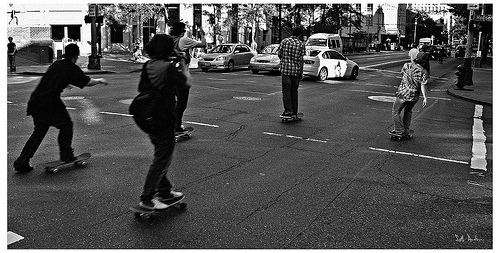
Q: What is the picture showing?
A: It is showing a road.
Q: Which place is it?
A: It is a road.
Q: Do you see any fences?
A: No, there are no fences.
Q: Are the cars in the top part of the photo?
A: Yes, the cars are in the top of the image.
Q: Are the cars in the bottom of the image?
A: No, the cars are in the top of the image.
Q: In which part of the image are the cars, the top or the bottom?
A: The cars are in the top of the image.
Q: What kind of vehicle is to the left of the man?
A: The vehicles are cars.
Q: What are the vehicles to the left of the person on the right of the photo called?
A: The vehicles are cars.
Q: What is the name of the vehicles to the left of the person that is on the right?
A: The vehicles are cars.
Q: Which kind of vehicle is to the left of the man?
A: The vehicles are cars.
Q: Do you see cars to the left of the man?
A: Yes, there are cars to the left of the man.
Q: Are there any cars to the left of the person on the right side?
A: Yes, there are cars to the left of the man.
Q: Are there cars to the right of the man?
A: No, the cars are to the left of the man.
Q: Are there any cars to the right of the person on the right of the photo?
A: No, the cars are to the left of the man.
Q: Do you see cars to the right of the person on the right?
A: No, the cars are to the left of the man.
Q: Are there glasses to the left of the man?
A: No, there are cars to the left of the man.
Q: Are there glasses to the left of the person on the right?
A: No, there are cars to the left of the man.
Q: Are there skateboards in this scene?
A: Yes, there is a skateboard.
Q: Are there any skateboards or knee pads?
A: Yes, there is a skateboard.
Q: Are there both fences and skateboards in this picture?
A: No, there is a skateboard but no fences.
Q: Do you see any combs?
A: No, there are no combs.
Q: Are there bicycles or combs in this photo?
A: No, there are no combs or bicycles.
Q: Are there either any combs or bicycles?
A: No, there are no combs or bicycles.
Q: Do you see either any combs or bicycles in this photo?
A: No, there are no combs or bicycles.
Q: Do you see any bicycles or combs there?
A: No, there are no combs or bicycles.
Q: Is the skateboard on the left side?
A: Yes, the skateboard is on the left of the image.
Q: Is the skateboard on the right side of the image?
A: No, the skateboard is on the left of the image.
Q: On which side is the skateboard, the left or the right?
A: The skateboard is on the left of the image.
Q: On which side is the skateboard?
A: The skateboard is on the left of the image.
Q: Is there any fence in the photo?
A: No, there are no fences.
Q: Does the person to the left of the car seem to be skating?
A: Yes, the person is skating.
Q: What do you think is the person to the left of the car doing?
A: The person is skating.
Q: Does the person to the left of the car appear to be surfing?
A: No, the person is skating.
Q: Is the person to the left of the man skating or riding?
A: The person is skating.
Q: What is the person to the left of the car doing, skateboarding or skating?
A: The person is skating.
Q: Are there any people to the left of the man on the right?
A: Yes, there is a person to the left of the man.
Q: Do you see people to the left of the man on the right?
A: Yes, there is a person to the left of the man.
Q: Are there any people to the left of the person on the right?
A: Yes, there is a person to the left of the man.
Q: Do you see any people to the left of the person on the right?
A: Yes, there is a person to the left of the man.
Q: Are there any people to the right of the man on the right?
A: No, the person is to the left of the man.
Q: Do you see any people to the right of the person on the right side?
A: No, the person is to the left of the man.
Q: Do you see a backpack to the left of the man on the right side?
A: No, there is a person to the left of the man.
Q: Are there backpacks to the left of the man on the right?
A: No, there is a person to the left of the man.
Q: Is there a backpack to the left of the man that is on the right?
A: No, there is a person to the left of the man.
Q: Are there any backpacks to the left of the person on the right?
A: No, there is a person to the left of the man.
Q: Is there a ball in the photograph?
A: No, there are no balls.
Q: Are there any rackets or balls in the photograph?
A: No, there are no balls or rackets.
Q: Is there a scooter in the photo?
A: No, there are no scooters.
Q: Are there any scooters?
A: No, there are no scooters.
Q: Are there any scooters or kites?
A: No, there are no scooters or kites.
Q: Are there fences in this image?
A: No, there are no fences.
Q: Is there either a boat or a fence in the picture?
A: No, there are no fences or boats.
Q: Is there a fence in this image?
A: No, there are no fences.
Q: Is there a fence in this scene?
A: No, there are no fences.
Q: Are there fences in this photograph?
A: No, there are no fences.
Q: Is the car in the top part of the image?
A: Yes, the car is in the top of the image.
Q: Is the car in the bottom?
A: No, the car is in the top of the image.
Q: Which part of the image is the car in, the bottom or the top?
A: The car is in the top of the image.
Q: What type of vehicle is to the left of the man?
A: The vehicle is a car.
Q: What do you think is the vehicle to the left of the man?
A: The vehicle is a car.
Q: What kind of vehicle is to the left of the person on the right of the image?
A: The vehicle is a car.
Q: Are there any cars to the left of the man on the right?
A: Yes, there is a car to the left of the man.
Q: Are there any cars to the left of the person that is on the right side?
A: Yes, there is a car to the left of the man.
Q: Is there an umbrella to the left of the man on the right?
A: No, there is a car to the left of the man.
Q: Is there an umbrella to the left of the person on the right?
A: No, there is a car to the left of the man.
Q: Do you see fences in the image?
A: No, there are no fences.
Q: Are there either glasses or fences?
A: No, there are no fences or glasses.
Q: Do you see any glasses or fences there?
A: No, there are no fences or glasses.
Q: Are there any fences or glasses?
A: No, there are no fences or glasses.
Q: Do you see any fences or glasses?
A: No, there are no fences or glasses.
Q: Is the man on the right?
A: Yes, the man is on the right of the image.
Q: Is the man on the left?
A: No, the man is on the right of the image.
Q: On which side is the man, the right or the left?
A: The man is on the right of the image.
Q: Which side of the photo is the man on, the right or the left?
A: The man is on the right of the image.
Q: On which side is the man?
A: The man is on the right of the image.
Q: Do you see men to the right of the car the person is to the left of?
A: Yes, there is a man to the right of the car.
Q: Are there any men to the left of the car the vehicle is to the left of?
A: No, the man is to the right of the car.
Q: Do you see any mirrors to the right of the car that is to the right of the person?
A: No, there is a man to the right of the car.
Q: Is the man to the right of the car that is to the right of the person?
A: Yes, the man is to the right of the car.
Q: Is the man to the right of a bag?
A: No, the man is to the right of the car.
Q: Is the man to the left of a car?
A: No, the man is to the right of a car.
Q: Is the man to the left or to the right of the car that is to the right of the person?
A: The man is to the right of the car.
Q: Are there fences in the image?
A: No, there are no fences.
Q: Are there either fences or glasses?
A: No, there are no fences or glasses.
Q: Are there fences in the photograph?
A: No, there are no fences.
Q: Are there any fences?
A: No, there are no fences.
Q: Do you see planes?
A: No, there are no planes.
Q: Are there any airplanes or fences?
A: No, there are no airplanes or fences.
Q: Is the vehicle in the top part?
A: Yes, the vehicle is in the top of the image.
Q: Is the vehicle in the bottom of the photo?
A: No, the vehicle is in the top of the image.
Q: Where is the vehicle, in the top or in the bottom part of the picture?
A: The vehicle is in the top of the image.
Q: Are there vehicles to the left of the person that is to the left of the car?
A: Yes, there is a vehicle to the left of the person.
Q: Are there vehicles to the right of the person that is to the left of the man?
A: No, the vehicle is to the left of the person.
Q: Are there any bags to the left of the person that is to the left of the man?
A: No, there is a vehicle to the left of the person.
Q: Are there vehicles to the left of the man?
A: Yes, there is a vehicle to the left of the man.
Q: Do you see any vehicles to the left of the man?
A: Yes, there is a vehicle to the left of the man.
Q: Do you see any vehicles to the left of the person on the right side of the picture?
A: Yes, there is a vehicle to the left of the man.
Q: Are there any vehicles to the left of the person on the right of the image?
A: Yes, there is a vehicle to the left of the man.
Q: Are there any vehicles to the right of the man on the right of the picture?
A: No, the vehicle is to the left of the man.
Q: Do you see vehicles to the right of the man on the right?
A: No, the vehicle is to the left of the man.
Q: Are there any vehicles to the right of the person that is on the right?
A: No, the vehicle is to the left of the man.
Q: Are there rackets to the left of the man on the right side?
A: No, there is a vehicle to the left of the man.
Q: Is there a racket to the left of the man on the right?
A: No, there is a vehicle to the left of the man.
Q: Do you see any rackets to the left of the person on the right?
A: No, there is a vehicle to the left of the man.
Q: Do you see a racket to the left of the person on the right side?
A: No, there is a vehicle to the left of the man.